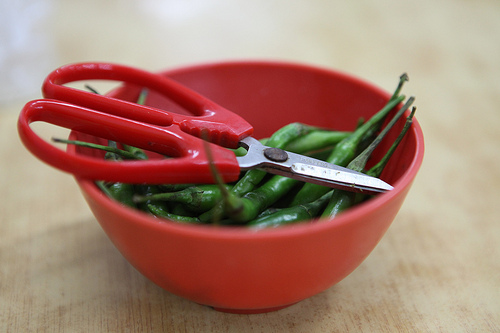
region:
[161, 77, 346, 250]
green beans in a bowl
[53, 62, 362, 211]
small shears on a bowl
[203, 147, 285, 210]
beans in a bowl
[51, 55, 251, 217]
red shears in a bowl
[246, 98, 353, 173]
green beans in a bowl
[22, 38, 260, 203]
shears in a bowl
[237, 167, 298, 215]
vegetables in a red bowl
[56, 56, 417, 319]
bowl on a table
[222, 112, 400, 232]
metal shears in a bowl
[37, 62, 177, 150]
red shears in a bowl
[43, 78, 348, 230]
scissor's handle is red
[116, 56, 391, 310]
a bowl of green chilis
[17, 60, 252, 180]
Red handle on pair of scissors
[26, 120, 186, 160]
Hole for fingers on handle of scissors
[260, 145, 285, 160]
Screw holding scissor blades together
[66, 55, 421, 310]
Red bowl sitting on table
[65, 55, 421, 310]
Red bowl filled with green beans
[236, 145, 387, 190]
Blades on pair of scissors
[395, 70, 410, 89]
Dark tip on green bean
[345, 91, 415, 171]
Withered edge of green bean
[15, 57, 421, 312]
Scissors sitting on top of bowl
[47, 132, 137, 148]
Stem of green bean underneath scissors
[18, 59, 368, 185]
A pair of red scissors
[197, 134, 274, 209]
A green fresh pepper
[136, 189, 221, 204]
A green fresh pepper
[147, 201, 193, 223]
A green fresh pepper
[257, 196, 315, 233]
A green fresh pepper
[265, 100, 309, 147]
A green fresh pepper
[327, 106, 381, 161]
A green fresh pepper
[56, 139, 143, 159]
A green fresh pepper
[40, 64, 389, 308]
A red bowl of green pepper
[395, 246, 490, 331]
A wooden table surface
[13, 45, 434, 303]
red bowl filled with beans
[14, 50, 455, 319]
cooked beans in a bowl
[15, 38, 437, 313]
red kitchen shears in a bowl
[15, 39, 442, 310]
kitchen shears in a bowl with beans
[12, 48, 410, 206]
red and silver kitchen shears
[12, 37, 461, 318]
red bowl on a wooden table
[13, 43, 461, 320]
bowl of green beans on a table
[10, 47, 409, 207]
scissors with red handles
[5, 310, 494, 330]
pale unfinished wood table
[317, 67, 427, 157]
green beans with the stems still attached